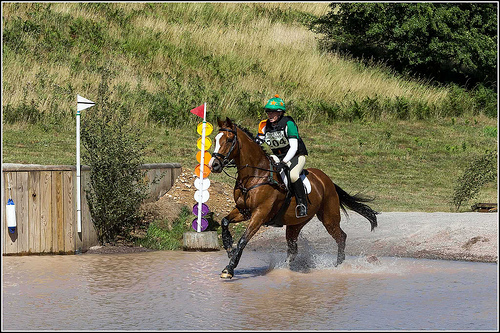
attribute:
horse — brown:
[207, 122, 352, 288]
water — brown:
[130, 254, 227, 325]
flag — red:
[183, 101, 211, 125]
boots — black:
[290, 179, 304, 222]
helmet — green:
[262, 92, 286, 112]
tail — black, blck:
[332, 181, 387, 236]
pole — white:
[73, 113, 89, 238]